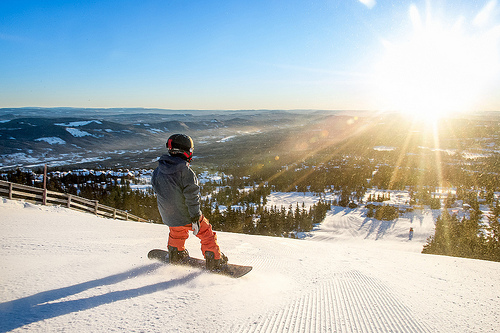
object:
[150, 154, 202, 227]
grey coat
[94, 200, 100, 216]
board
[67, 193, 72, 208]
board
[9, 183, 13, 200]
board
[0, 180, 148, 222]
fence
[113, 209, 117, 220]
board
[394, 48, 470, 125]
sun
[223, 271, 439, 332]
straight lines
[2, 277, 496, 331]
snow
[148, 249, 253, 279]
snowboard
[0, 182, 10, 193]
wooden board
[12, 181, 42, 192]
wooden board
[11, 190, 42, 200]
wooden board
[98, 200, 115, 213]
wooden board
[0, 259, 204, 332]
shadow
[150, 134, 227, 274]
boy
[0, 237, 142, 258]
tracks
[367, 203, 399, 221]
trees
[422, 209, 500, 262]
trees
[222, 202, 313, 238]
trees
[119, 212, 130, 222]
wooden board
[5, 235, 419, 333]
hill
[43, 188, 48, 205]
board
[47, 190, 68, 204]
board